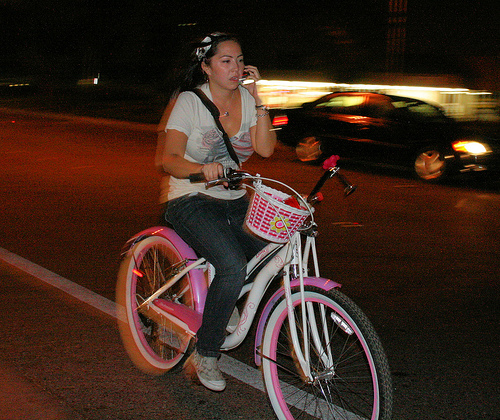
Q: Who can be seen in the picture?
A: A woman.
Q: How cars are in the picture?
A: One.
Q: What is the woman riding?
A: A bike.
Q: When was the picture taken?
A: Nighttime.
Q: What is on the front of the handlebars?
A: A basket.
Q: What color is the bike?
A: Pink & white.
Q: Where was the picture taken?
A: The road.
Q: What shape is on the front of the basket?
A: A flower.